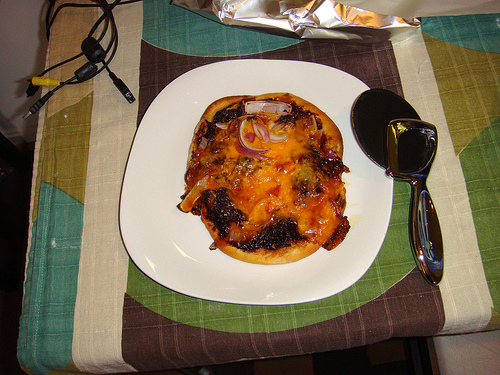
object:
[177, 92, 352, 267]
pizza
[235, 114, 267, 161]
onion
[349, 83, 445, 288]
pizza cutter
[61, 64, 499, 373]
tablecloth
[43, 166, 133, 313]
design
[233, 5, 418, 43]
foil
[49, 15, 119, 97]
wires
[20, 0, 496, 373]
table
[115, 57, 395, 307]
plate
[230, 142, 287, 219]
cheese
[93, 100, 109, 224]
white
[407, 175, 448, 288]
handle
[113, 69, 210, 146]
edges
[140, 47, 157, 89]
brown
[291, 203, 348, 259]
crust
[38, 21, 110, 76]
cords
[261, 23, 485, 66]
stripes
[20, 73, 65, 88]
yellow tip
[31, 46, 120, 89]
cord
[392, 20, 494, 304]
stripe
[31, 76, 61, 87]
cover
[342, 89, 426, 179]
blade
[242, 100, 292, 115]
onions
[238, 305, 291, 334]
green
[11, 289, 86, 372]
corner